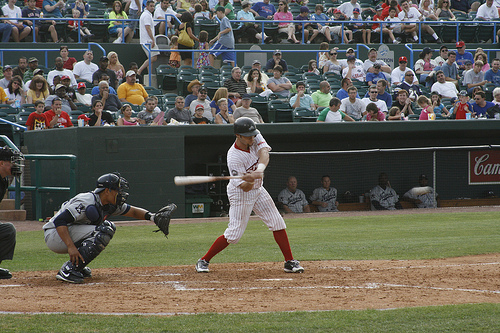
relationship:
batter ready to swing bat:
[175, 116, 318, 279] [166, 173, 243, 185]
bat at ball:
[166, 173, 243, 185] [413, 185, 434, 203]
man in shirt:
[117, 64, 151, 110] [116, 83, 149, 105]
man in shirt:
[309, 73, 335, 109] [309, 90, 337, 112]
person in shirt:
[104, 0, 130, 29] [106, 10, 130, 28]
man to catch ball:
[40, 170, 163, 283] [410, 183, 435, 199]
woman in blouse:
[270, 0, 298, 31] [270, 13, 293, 24]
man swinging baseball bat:
[216, 116, 295, 239] [181, 167, 213, 192]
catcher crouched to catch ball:
[77, 162, 206, 315] [326, 200, 338, 220]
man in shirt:
[116, 69, 149, 106] [124, 80, 144, 99]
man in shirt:
[311, 80, 333, 107] [314, 90, 329, 105]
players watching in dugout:
[302, 174, 352, 216] [347, 157, 408, 218]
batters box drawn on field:
[195, 246, 257, 306] [407, 269, 436, 317]